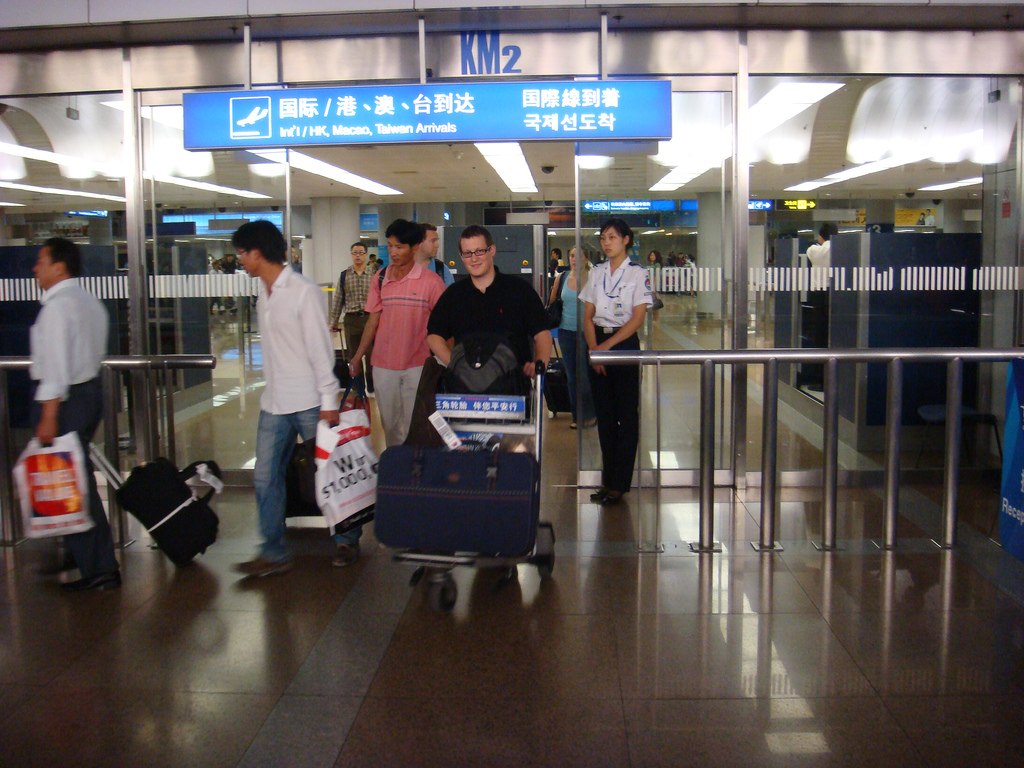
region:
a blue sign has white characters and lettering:
[183, 76, 671, 154]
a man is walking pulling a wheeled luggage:
[14, 232, 220, 594]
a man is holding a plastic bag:
[8, 400, 103, 556]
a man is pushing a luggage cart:
[389, 233, 557, 576]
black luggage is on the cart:
[372, 369, 550, 589]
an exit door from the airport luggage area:
[9, 50, 1011, 736]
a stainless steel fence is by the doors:
[32, 328, 1022, 598]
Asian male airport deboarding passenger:
[227, 218, 338, 583]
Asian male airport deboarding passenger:
[25, 233, 114, 591]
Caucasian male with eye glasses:
[451, 228, 547, 397]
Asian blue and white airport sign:
[180, 89, 675, 141]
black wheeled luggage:
[85, 436, 226, 567]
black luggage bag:
[372, 440, 549, 562]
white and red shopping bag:
[9, 435, 96, 543]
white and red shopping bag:
[312, 408, 386, 527]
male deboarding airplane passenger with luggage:
[328, 240, 377, 390]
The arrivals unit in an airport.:
[0, 0, 1021, 765]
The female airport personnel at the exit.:
[583, 220, 645, 497]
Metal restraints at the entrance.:
[589, 308, 1020, 542]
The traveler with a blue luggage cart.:
[370, 223, 560, 604]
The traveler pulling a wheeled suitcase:
[21, 235, 219, 568]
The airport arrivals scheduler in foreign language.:
[184, 78, 675, 142]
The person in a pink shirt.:
[349, 222, 444, 439]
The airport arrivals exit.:
[0, 0, 1023, 767]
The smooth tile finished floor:
[0, 321, 1023, 765]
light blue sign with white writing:
[177, 70, 668, 157]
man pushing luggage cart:
[395, 219, 564, 586]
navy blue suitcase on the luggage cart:
[380, 458, 535, 554]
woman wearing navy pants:
[578, 216, 659, 493]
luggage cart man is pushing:
[373, 354, 550, 599]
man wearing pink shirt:
[354, 228, 453, 517]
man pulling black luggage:
[13, 231, 229, 585]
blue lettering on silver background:
[451, 19, 524, 74]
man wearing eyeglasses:
[420, 224, 583, 449]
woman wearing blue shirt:
[555, 231, 619, 416]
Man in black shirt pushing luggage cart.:
[370, 226, 545, 593]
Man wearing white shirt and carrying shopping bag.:
[224, 218, 377, 588]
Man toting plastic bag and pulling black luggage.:
[16, 237, 229, 604]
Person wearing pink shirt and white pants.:
[358, 215, 441, 437]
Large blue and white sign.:
[173, 74, 693, 145]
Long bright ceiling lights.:
[631, 23, 1020, 210]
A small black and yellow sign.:
[774, 188, 825, 218]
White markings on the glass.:
[653, 257, 1020, 293]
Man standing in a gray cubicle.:
[774, 212, 972, 427]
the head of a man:
[430, 230, 503, 303]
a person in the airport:
[406, 218, 572, 659]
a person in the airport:
[207, 271, 332, 566]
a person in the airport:
[354, 274, 485, 505]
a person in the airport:
[336, 241, 371, 340]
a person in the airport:
[555, 221, 645, 399]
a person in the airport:
[345, 218, 482, 340]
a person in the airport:
[219, 203, 303, 489]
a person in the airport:
[365, 253, 441, 469]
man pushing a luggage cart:
[373, 233, 564, 595]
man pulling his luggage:
[2, 236, 222, 584]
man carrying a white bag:
[213, 215, 385, 588]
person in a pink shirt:
[336, 217, 451, 451]